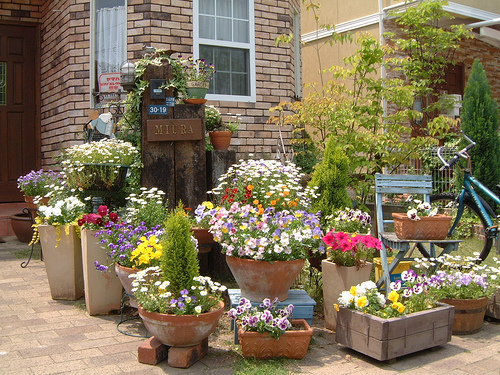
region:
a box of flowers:
[332, 283, 455, 364]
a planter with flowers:
[228, 293, 315, 360]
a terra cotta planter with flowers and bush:
[135, 203, 223, 348]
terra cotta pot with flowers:
[205, 203, 322, 299]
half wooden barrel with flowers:
[429, 271, 487, 334]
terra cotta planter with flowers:
[390, 203, 455, 238]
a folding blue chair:
[372, 166, 454, 285]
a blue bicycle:
[415, 140, 497, 265]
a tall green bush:
[458, 56, 497, 196]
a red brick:
[135, 336, 165, 364]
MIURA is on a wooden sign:
[146, 112, 201, 146]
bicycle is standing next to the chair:
[421, 138, 499, 254]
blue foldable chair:
[361, 170, 454, 276]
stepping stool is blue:
[214, 267, 323, 328]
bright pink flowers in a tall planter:
[321, 230, 387, 275]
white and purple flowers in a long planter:
[393, 202, 478, 240]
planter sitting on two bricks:
[130, 325, 183, 371]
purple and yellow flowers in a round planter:
[99, 215, 168, 269]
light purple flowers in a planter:
[13, 174, 67, 195]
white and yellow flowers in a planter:
[332, 281, 400, 355]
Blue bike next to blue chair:
[412, 125, 499, 277]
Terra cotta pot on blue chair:
[387, 210, 448, 236]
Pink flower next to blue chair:
[370, 235, 380, 247]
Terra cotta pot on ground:
[237, 317, 309, 360]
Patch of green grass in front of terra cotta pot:
[237, 358, 284, 373]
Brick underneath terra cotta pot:
[167, 337, 208, 368]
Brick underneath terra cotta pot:
[135, 330, 165, 365]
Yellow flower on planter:
[391, 297, 407, 317]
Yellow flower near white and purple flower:
[382, 286, 402, 303]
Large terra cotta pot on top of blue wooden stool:
[225, 251, 302, 301]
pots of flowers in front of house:
[15, 45, 490, 355]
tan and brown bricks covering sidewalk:
[10, 256, 120, 357]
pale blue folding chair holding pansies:
[365, 166, 455, 286]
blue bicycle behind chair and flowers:
[415, 126, 495, 261]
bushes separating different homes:
[270, 15, 495, 185]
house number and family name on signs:
[135, 85, 205, 140]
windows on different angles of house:
[40, 0, 280, 105]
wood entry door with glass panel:
[0, 10, 40, 201]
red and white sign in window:
[90, 70, 125, 95]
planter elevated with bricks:
[135, 301, 210, 367]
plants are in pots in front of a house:
[11, 1, 495, 373]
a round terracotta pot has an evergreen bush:
[133, 200, 221, 341]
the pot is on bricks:
[131, 304, 221, 369]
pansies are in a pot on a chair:
[391, 198, 451, 240]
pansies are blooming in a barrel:
[428, 268, 493, 338]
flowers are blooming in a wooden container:
[332, 279, 452, 361]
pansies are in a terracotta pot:
[208, 206, 315, 308]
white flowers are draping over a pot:
[53, 133, 141, 203]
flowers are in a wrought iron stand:
[16, 168, 48, 273]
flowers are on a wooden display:
[136, 56, 212, 259]